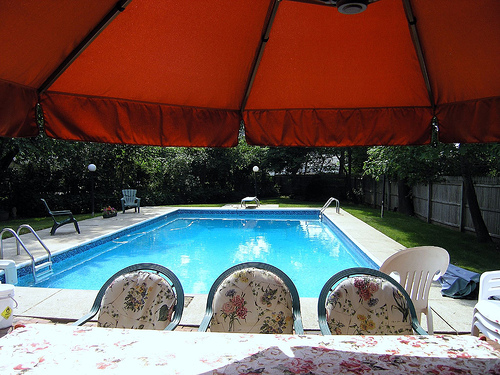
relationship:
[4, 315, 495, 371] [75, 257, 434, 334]
table near chairs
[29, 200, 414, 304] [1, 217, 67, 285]
pool has ladder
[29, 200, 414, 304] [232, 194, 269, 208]
pool has board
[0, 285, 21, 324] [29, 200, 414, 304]
bucket near pool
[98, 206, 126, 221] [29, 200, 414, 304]
plant near pool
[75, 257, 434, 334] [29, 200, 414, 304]
chairs near pool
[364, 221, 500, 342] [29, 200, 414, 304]
chair near pool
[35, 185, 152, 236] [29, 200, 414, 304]
chair near pool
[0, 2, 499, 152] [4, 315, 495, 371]
umbrella above table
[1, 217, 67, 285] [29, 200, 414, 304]
ladder in pool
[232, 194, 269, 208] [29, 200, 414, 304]
board near pool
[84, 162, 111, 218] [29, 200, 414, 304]
pole near pool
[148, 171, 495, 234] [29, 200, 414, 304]
fence surrounding pool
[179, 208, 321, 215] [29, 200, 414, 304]
tile surrounding pool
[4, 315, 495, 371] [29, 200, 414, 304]
table near pool